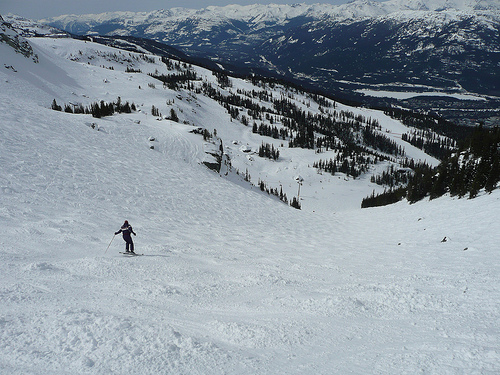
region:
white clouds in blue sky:
[390, 49, 451, 96]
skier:
[104, 202, 138, 253]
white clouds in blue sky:
[424, 16, 491, 58]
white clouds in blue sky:
[255, 2, 306, 44]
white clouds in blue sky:
[292, 23, 350, 61]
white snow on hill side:
[227, 295, 284, 327]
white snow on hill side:
[342, 268, 370, 295]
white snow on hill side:
[340, 253, 417, 325]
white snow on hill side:
[235, 308, 279, 349]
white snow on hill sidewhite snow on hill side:
[191, 282, 223, 312]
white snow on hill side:
[71, 311, 139, 362]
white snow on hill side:
[261, 268, 323, 315]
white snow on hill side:
[197, 229, 259, 284]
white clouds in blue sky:
[178, 6, 203, 34]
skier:
[100, 211, 160, 263]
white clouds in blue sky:
[27, 15, 87, 43]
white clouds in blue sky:
[125, 13, 192, 55]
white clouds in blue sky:
[330, 22, 388, 53]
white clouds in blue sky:
[444, 11, 488, 51]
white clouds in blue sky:
[310, 3, 350, 53]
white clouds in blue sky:
[255, 1, 310, 42]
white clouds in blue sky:
[178, 18, 232, 59]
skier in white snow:
[84, 203, 162, 274]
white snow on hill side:
[160, 11, 262, 78]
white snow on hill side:
[392, 19, 466, 49]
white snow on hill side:
[342, 19, 406, 70]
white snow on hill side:
[281, 9, 345, 53]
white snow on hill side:
[247, 3, 282, 27]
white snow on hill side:
[192, 9, 247, 43]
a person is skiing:
[117, 220, 143, 258]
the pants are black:
[123, 236, 139, 253]